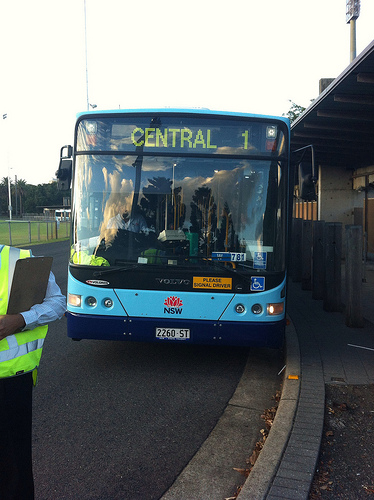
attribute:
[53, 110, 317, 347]
bus — blue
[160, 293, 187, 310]
flower — red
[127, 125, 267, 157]
sign — yellow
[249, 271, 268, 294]
sign — blue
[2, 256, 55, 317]
clipbaord — brown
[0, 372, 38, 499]
pants — black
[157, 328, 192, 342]
license plate — white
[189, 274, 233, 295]
sticker — orange